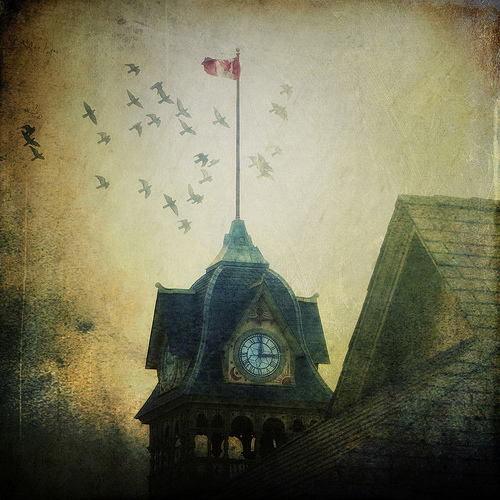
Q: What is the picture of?
A: A clock tower.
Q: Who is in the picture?
A: No one.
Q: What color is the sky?
A: Yellow.